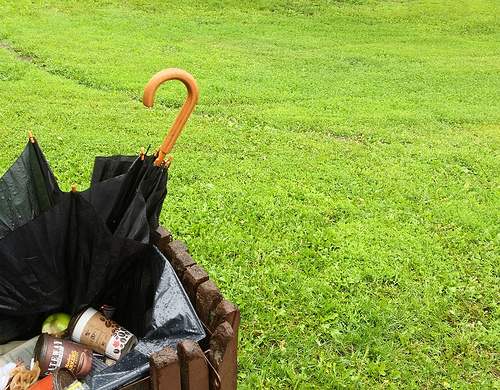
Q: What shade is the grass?
A: Green.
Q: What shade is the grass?
A: Green.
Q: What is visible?
A: The grass.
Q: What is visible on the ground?
A: The grass.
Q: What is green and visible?
A: The grass.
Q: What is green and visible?
A: The grass.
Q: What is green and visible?
A: The grass.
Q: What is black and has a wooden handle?
A: An umbrella.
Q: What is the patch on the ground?
A: Grass.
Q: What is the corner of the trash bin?
A: Brown.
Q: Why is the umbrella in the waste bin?
A: Broken.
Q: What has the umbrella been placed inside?
A: Trash bin.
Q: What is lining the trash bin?
A: Plastic bag.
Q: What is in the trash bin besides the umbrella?
A: Coffee cups.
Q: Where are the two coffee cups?
A: Trash can.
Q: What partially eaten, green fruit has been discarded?
A: Apple.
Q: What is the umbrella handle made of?
A: Wood.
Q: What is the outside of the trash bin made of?
A: Wood.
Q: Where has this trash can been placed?
A: Green field.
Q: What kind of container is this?
A: Trash can.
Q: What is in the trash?
A: Umbrella and cups.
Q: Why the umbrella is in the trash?
A: It is broken.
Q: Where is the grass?
A: On the ground.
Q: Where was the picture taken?
A: In a field.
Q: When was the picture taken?
A: During the daytime.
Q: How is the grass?
A: Very thick.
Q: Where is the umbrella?
A: In a trash bin.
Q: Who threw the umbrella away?
A: The angry man.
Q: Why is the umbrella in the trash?
A: It was not working.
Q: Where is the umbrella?
A: In the trash.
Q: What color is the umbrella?
A: Black with a brown handle.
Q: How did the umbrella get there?
A: Someone threw it away.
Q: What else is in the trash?
A: Coffee cups and and apple.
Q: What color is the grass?
A: Green.